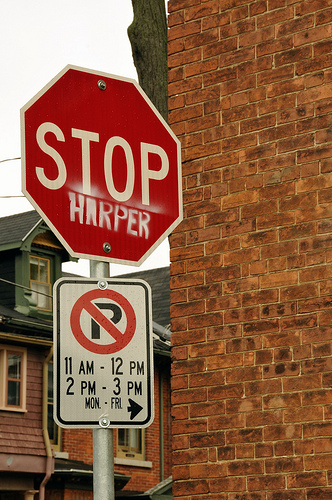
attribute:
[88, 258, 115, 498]
pipe — painted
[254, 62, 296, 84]
brick — red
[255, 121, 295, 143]
brick — red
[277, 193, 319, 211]
brick — red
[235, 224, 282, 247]
brick — red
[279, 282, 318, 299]
brick — red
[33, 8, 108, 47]
sky — clear, white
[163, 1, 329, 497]
building — brown, brick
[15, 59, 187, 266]
sign — red, white, stop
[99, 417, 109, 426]
screw — silver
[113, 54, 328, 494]
building — red , brick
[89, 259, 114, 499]
pole — silver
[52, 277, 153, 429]
sign — parking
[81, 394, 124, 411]
lettering — black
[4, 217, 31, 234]
shingles — black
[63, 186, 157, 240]
harper — spray painted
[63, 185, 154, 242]
spray paint — white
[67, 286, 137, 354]
letter p — crossed out